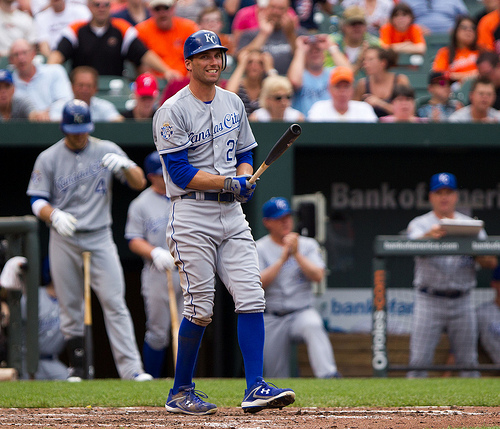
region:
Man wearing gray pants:
[161, 199, 244, 319]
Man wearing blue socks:
[175, 315, 273, 392]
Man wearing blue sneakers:
[158, 383, 223, 420]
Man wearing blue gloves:
[226, 162, 312, 195]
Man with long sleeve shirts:
[153, 134, 211, 196]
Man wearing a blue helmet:
[183, 28, 240, 84]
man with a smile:
[186, 46, 246, 95]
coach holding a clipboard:
[385, 160, 491, 327]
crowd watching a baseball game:
[281, 24, 395, 96]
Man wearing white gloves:
[88, 150, 140, 192]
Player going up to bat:
[152, 29, 302, 411]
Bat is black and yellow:
[248, 124, 299, 181]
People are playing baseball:
[27, 30, 484, 377]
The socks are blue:
[171, 312, 263, 388]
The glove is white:
[50, 209, 78, 236]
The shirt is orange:
[134, 16, 197, 76]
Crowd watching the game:
[0, 1, 497, 121]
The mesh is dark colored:
[384, 256, 496, 365]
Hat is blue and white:
[432, 172, 456, 188]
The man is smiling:
[183, 30, 225, 82]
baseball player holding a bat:
[152, 14, 308, 421]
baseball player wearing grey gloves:
[136, 18, 336, 424]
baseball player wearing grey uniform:
[139, 11, 321, 410]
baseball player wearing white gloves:
[35, 77, 155, 396]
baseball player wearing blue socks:
[146, 20, 301, 409]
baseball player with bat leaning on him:
[36, 87, 156, 377]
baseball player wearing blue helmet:
[32, 85, 135, 202]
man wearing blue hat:
[400, 150, 482, 263]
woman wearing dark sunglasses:
[254, 63, 311, 140]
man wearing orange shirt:
[133, 3, 212, 76]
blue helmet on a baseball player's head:
[182, 28, 229, 60]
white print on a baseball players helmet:
[200, 33, 222, 45]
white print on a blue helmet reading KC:
[201, 32, 218, 45]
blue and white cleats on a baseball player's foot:
[239, 374, 297, 416]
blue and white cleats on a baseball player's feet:
[163, 374, 297, 415]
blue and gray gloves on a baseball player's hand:
[220, 175, 255, 195]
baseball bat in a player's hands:
[246, 121, 304, 183]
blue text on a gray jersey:
[187, 113, 244, 147]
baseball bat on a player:
[80, 246, 95, 373]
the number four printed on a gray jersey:
[91, 178, 107, 197]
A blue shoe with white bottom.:
[241, 380, 296, 412]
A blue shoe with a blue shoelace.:
[163, 388, 217, 415]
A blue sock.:
[236, 309, 263, 384]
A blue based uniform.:
[151, 84, 265, 387]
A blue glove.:
[225, 176, 256, 193]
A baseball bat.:
[248, 122, 302, 186]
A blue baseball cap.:
[262, 196, 292, 218]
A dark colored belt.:
[181, 189, 237, 201]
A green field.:
[1, 379, 498, 406]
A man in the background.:
[28, 100, 151, 380]